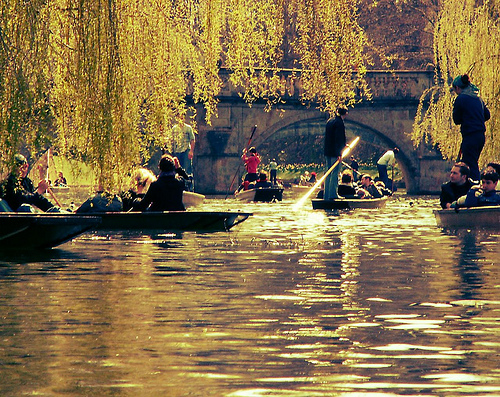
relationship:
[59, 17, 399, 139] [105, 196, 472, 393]
tree over river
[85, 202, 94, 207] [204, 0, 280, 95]
leaf on branches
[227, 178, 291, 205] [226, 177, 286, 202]
stern of a row boat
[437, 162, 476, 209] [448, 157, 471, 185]
people has a head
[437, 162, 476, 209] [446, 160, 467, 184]
people has a head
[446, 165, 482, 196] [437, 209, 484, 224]
people are in boat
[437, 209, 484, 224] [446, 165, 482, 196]
boat has people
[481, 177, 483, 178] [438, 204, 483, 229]
person on boat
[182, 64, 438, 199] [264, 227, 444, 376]
bridge over water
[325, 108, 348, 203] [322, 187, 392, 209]
man standing on back of boat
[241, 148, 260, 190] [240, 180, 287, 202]
person in boat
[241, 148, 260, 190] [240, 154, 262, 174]
person has a coat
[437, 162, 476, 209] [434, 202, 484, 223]
people are sitting in a boat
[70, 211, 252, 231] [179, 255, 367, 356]
boat in water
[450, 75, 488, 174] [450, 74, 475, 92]
person wearing a bandana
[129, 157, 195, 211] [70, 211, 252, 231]
person sitting inside a boat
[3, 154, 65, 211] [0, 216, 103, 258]
people sitting inside a boat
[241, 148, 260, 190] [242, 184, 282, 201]
person sitting inside a row boat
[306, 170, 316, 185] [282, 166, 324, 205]
person sitting inside a row boat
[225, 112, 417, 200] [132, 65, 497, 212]
archway under bridge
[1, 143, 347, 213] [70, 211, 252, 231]
people in boat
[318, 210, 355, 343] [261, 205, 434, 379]
reflection on water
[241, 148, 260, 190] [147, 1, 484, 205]
person seen in background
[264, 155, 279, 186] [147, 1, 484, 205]
person seen in background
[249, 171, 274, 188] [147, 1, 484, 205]
person seen in background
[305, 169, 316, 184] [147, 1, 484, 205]
person seen in background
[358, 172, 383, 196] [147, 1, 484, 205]
person seen in background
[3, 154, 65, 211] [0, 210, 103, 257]
people sitting inside boat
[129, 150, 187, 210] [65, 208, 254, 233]
person sitting inside boat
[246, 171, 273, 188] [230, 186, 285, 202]
person sitting inside boat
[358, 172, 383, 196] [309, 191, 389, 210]
person sitting inside boat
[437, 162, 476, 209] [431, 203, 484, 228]
people sitting inside boat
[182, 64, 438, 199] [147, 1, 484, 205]
bridge seen in background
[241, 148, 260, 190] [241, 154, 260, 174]
person wearing shirt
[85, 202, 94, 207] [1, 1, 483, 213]
leaf hanging in background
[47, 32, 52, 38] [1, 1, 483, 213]
leaf hanging in background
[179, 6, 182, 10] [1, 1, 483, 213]
leaf hanging in background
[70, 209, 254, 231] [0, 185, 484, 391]
boat floating in water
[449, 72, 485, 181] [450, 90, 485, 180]
person wearing black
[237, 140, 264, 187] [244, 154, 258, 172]
person wears coat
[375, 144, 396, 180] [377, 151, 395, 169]
person wears shirt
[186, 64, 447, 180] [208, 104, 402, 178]
bridge has archway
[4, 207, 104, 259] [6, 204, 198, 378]
boat in water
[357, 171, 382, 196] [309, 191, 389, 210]
person in boat